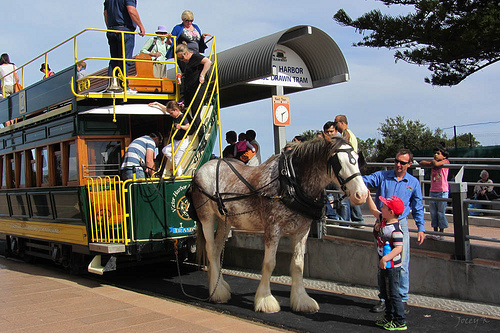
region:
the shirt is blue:
[355, 152, 430, 239]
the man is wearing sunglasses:
[386, 146, 436, 186]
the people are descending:
[95, 16, 279, 218]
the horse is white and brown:
[41, 85, 391, 314]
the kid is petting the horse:
[340, 155, 440, 315]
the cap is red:
[371, 187, 414, 217]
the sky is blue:
[201, 9, 266, 44]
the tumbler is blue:
[365, 225, 396, 290]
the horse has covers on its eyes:
[311, 130, 373, 215]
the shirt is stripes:
[104, 130, 161, 206]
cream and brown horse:
[177, 111, 380, 318]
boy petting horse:
[360, 177, 442, 332]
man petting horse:
[357, 130, 446, 314]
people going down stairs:
[115, 0, 219, 201]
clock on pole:
[267, 82, 297, 128]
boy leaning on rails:
[406, 137, 473, 235]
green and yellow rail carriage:
[0, 25, 227, 301]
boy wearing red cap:
[369, 179, 416, 244]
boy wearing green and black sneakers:
[371, 309, 425, 331]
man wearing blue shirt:
[347, 147, 452, 261]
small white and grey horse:
[185, 126, 370, 318]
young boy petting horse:
[327, 134, 435, 330]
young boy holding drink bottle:
[377, 196, 415, 332]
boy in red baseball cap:
[372, 193, 410, 225]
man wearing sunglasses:
[382, 146, 422, 189]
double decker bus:
[0, 28, 230, 254]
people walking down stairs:
[145, 7, 222, 184]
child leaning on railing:
[422, 145, 454, 244]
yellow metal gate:
[78, 171, 138, 254]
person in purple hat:
[140, 26, 174, 82]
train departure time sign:
[271, 94, 291, 126]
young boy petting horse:
[366, 188, 408, 330]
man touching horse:
[345, 146, 426, 313]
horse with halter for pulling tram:
[186, 128, 371, 313]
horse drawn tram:
[1, 26, 368, 316]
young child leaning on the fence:
[419, 146, 451, 238]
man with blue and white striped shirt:
[118, 127, 157, 178]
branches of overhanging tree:
[331, 1, 498, 88]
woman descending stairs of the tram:
[173, 41, 213, 150]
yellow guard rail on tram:
[86, 173, 125, 246]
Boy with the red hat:
[376, 194, 411, 331]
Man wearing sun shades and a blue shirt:
[385, 152, 415, 193]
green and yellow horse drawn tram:
[80, 74, 367, 314]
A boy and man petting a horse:
[269, 131, 429, 331]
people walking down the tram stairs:
[106, 28, 213, 239]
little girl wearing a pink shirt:
[421, 150, 453, 194]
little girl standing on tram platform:
[415, 144, 481, 246]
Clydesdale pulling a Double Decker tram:
[78, 114, 357, 313]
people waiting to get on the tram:
[222, 127, 262, 158]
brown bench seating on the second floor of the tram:
[76, 28, 173, 276]